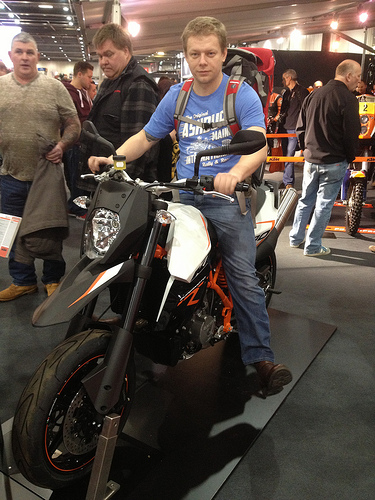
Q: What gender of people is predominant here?
A: Male.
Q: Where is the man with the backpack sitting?
A: On a motorcycle.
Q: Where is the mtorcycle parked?
A: Inside a building.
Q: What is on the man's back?
A: Backpack.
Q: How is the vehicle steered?
A: Handle bars.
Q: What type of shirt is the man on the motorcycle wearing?
A: T-shirt.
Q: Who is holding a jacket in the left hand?
A: The man to the far left.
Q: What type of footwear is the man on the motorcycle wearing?
A: Boots.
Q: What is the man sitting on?
A: Motorcycle.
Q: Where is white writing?
A: On blue shirt.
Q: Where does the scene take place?
A: In motorcycle showroom.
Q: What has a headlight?
A: Motorbike.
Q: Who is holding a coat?
A: Man on the left.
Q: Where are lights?
A: On the ceiling.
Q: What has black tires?
A: The motorbikes.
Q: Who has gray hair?
A: Man holding coat.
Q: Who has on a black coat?
A: Man on the right.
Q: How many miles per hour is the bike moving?
A: 0 MPH.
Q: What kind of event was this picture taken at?
A: Expo.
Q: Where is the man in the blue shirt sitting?
A: Motorcycle.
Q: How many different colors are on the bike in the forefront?
A: 3.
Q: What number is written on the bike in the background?
A: 2.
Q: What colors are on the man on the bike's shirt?
A: Blue and white.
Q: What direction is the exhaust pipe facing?
A: Up.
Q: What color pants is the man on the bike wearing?
A: Blue.